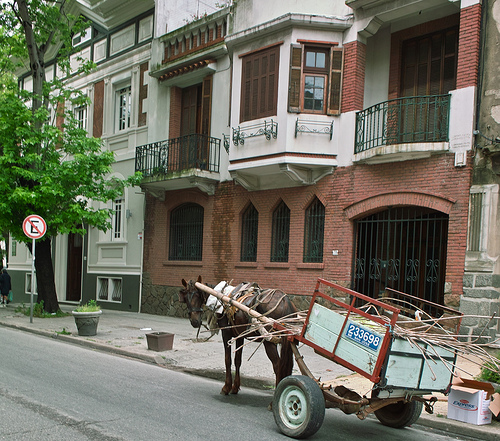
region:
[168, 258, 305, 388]
a horse attached to a cart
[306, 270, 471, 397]
a cart with straw in it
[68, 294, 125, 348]
a planter with a green plant inside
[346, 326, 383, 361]
a license plate on the cart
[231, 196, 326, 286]
three pointed windows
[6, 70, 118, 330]
a medium sized tree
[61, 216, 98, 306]
a brown door with a glass insert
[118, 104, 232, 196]
a metal balcony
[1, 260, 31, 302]
a person dressed in black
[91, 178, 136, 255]
a window framed in white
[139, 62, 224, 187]
balcony on second floor room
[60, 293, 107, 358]
flower pot on city street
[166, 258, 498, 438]
brown horse pulling cart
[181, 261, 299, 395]
brown horse standing on city street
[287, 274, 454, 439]
wooden cart with tree limbs in it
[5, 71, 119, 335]
tree with leaves on city sidewalk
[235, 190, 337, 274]
decorative iron window coverings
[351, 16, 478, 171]
balcony to a second floor room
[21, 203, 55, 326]
red and white directional sign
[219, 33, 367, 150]
windows to second story window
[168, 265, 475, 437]
Horse pulling branches on street.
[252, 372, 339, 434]
Black round tire of cargo.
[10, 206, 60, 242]
Circular street sign with a line across E.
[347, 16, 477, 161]
Balcony of a building.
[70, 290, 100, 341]
Planter on the sidewalk.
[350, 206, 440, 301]
Wrought iron gate on building.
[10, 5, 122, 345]
Trees on the sidewalk.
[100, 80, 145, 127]
Window of a building.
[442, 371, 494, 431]
Cardboard box on sidewalk.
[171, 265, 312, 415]
Brown horse on street.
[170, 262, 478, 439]
Horse pulling a cart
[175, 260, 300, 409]
Horse id brown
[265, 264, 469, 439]
Cart is small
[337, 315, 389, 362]
Cart has a tag on left side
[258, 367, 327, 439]
Wheel of cart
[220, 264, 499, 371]
Sticks on a cart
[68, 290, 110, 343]
Pot on side walk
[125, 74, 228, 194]
Balcony in a building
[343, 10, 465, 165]
Balcony in front of a screen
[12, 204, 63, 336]
Sign on right side of street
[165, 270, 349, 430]
Horse standing at the curb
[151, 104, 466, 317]
Red brick building with gated doors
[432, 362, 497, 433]
Opened white box sitting on side walk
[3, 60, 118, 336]
Tall green tree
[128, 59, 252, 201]
Small gated terrace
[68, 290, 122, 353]
Beige planter sitting on sidewalk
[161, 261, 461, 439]
Horse waiting with cart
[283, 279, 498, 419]
White cart full of sticks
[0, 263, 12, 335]
Person standing on the sidewalk